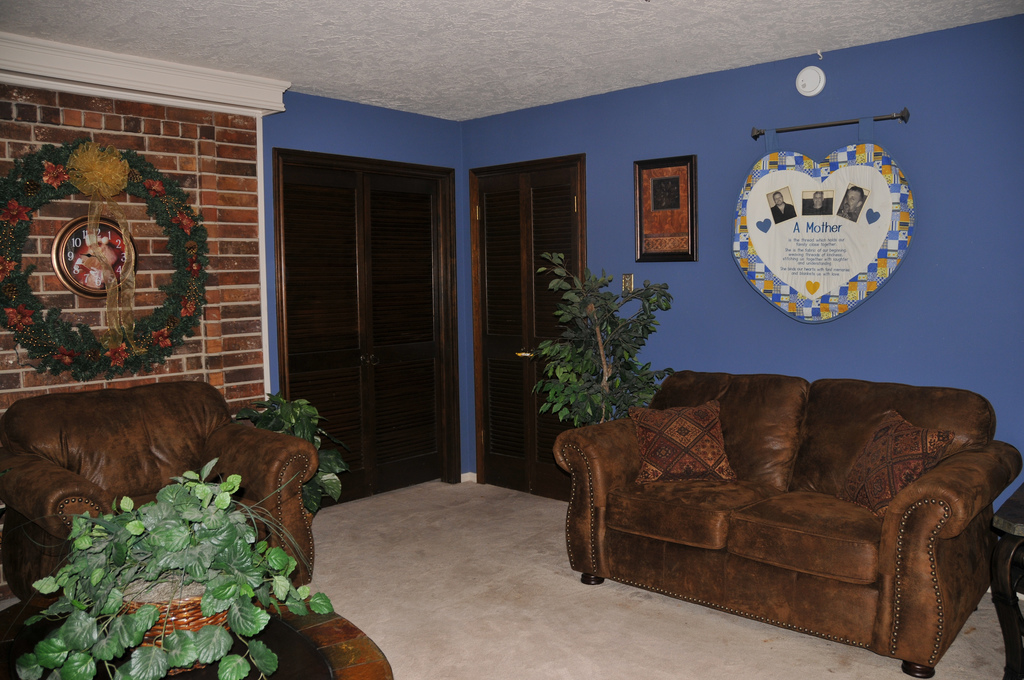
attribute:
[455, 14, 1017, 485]
wall — blue 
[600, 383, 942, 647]
seat — BROWN, LOVE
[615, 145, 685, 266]
picture — FRAMED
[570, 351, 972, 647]
seat — LOVE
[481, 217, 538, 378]
door — BROWN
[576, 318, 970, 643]
seat — LOVE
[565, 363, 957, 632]
seat — LOVE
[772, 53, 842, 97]
alarm — FIRE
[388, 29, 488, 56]
ceiling — WHITE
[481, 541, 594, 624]
carpet — white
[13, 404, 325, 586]
chair — leather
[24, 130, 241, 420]
wreath — green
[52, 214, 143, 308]
clock — round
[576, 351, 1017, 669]
couch — brown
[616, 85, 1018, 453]
wall — blue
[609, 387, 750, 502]
pillow — square